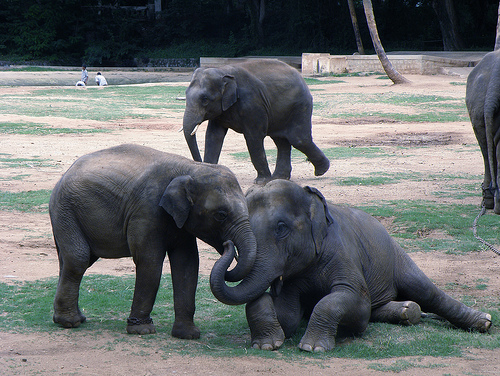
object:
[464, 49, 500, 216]
elephants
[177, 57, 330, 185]
elephants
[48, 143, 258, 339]
elephant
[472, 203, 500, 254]
chain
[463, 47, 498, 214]
chain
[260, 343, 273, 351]
nails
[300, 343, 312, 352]
nails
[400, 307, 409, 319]
nails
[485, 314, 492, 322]
nails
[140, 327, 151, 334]
nails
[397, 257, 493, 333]
leg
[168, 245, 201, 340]
leg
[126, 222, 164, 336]
leg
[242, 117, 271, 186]
leg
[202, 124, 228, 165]
leg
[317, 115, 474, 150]
patch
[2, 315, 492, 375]
dirt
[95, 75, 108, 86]
shirt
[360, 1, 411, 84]
tree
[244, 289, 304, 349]
leg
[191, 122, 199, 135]
tusk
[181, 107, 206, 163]
trunks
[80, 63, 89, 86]
person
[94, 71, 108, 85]
people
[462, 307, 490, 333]
elephant foot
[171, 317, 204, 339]
elephant foot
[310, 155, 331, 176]
elephant foot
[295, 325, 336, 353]
elephant foot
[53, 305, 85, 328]
elephant foot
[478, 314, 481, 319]
part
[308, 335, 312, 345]
part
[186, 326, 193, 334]
part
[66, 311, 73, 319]
part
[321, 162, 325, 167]
part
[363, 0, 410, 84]
trunk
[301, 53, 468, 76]
wall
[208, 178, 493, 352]
elephants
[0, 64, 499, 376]
field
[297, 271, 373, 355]
leg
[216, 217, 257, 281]
trunk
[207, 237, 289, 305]
trunk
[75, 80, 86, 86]
people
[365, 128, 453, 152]
mud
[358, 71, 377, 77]
stone